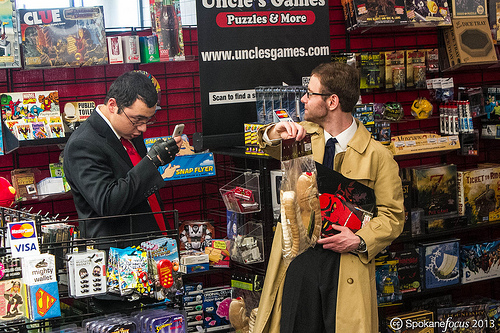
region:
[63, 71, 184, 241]
man is looking at his phone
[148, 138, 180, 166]
black finger-less glove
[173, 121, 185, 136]
phone is gray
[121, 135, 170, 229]
long ed necktie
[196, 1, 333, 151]
black banner hanging on wall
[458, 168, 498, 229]
board game next to board game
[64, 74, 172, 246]
man wearing a black jacket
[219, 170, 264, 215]
clear plexiglass bin is hanging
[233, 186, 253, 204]
red object inside clear bin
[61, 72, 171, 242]
man wearing glasses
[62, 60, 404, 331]
the two men in the store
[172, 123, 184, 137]
the cell phone in the man's hand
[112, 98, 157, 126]
the glasses on the man's face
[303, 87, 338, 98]
the glasses on the man's face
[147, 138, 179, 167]
the fingerless gloves on the man's hand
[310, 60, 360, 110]
the hair on the man's head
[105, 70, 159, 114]
the hair on the man's head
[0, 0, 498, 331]
the products in the store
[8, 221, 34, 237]
the log for Mastercard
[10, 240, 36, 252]
the logo for VISA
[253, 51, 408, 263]
The man is wearing glasses.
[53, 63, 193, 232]
The man is wearing glasses.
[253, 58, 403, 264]
The man is wearing a watch on his left wrist.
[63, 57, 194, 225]
The man is holding a cell phone.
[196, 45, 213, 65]
The letter is white.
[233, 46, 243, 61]
The letter is white.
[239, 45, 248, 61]
The letter is white.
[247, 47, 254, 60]
The letter is white.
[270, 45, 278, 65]
The letter is white.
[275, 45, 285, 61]
The letter is white.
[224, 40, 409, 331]
A man in the foreground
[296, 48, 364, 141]
A side view of a man's head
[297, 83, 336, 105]
Man is wearing eyeglasses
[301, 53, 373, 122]
Man has dark colored hair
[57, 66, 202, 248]
Man is looking at his phone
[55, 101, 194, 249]
Man is wearing a black suit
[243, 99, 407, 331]
Man is wearing a tan colored coat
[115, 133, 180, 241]
Man is wearing a red tie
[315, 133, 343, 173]
Man is wearing a dark colored tie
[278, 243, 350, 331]
Man is wearing black dress pants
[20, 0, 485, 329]
two men standing in store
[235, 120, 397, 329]
man wearing trench coat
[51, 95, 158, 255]
man wearing black coat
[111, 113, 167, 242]
man wearing red tie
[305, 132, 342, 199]
man wearing black tie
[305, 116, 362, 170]
man has white collar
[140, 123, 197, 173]
man wearing finger-less glove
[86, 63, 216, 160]
man looking at phone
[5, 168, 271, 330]
multiple items on display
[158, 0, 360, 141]
black and white sign